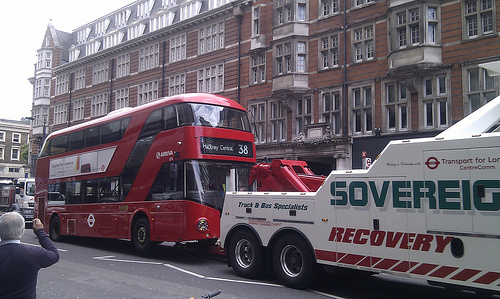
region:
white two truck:
[216, 95, 498, 297]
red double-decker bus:
[32, 90, 259, 248]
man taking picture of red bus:
[1, 207, 58, 297]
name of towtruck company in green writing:
[326, 176, 499, 216]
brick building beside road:
[28, 0, 498, 172]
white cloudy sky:
[0, 0, 137, 124]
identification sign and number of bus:
[198, 135, 255, 155]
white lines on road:
[18, 240, 336, 297]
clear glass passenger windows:
[42, 171, 131, 209]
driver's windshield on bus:
[185, 160, 254, 207]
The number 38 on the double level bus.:
[235, 145, 250, 154]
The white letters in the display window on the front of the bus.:
[201, 135, 238, 151]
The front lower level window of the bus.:
[188, 160, 257, 207]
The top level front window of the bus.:
[170, 98, 250, 129]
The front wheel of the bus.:
[128, 215, 154, 248]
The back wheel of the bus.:
[47, 215, 64, 237]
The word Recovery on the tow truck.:
[327, 217, 469, 264]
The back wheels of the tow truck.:
[226, 218, 313, 280]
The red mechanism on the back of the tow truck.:
[252, 146, 319, 189]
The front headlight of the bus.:
[197, 214, 208, 232]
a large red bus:
[31, 91, 256, 247]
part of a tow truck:
[213, 93, 498, 298]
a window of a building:
[425, 100, 433, 127]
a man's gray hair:
[0, 210, 33, 240]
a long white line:
[90, 245, 272, 287]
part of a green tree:
[20, 141, 29, 159]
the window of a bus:
[178, 99, 249, 126]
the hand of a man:
[31, 212, 46, 229]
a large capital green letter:
[328, 177, 349, 208]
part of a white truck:
[17, 176, 38, 219]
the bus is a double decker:
[38, 90, 253, 257]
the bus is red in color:
[37, 93, 256, 253]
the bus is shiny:
[38, 93, 255, 250]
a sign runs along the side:
[48, 143, 117, 181]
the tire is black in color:
[228, 227, 260, 274]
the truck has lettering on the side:
[332, 173, 497, 218]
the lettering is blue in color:
[329, 175, 498, 215]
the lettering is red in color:
[328, 224, 450, 255]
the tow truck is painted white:
[221, 126, 496, 289]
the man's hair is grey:
[1, 210, 23, 239]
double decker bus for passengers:
[22, 90, 268, 253]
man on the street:
[0, 199, 64, 296]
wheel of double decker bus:
[120, 214, 154, 250]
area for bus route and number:
[196, 133, 259, 160]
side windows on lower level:
[63, 182, 120, 204]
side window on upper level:
[46, 139, 68, 151]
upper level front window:
[193, 107, 250, 128]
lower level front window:
[183, 161, 252, 202]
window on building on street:
[138, 46, 159, 68]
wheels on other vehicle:
[225, 228, 315, 283]